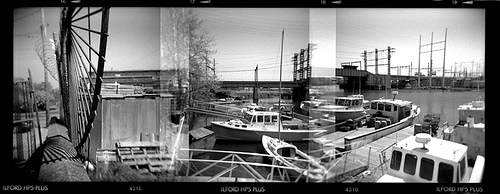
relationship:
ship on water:
[205, 105, 324, 148] [124, 102, 303, 160]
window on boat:
[386, 147, 402, 174] [364, 127, 484, 181]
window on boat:
[258, 115, 264, 123] [205, 108, 324, 144]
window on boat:
[264, 113, 271, 123] [199, 110, 319, 150]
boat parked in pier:
[453, 94, 482, 124] [10, 65, 487, 184]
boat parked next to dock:
[260, 134, 332, 181] [165, 145, 329, 192]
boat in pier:
[260, 134, 332, 181] [10, 65, 487, 184]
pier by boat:
[297, 102, 420, 182] [260, 134, 332, 181]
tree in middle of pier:
[157, 4, 221, 116] [11, 85, 485, 175]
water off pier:
[321, 85, 486, 126] [185, 89, 422, 184]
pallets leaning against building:
[113, 139, 177, 172] [85, 83, 175, 169]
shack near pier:
[89, 76, 172, 165] [185, 89, 422, 184]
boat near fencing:
[261, 134, 334, 184] [165, 143, 344, 183]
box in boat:
[375, 118, 388, 129] [311, 97, 415, 153]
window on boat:
[386, 147, 402, 174] [367, 129, 489, 184]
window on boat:
[417, 156, 436, 180] [375, 130, 485, 184]